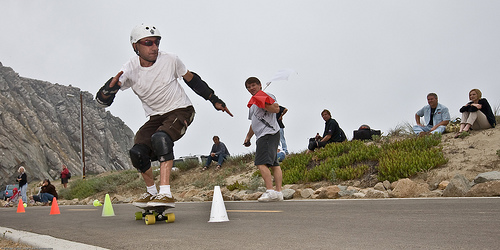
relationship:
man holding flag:
[235, 73, 293, 207] [242, 87, 283, 119]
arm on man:
[92, 64, 131, 106] [91, 18, 232, 207]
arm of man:
[184, 70, 235, 119] [97, 21, 234, 227]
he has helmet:
[94, 21, 235, 205] [127, 23, 161, 44]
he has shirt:
[94, 21, 235, 205] [114, 50, 192, 115]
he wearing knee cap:
[94, 25, 236, 202] [151, 126, 175, 168]